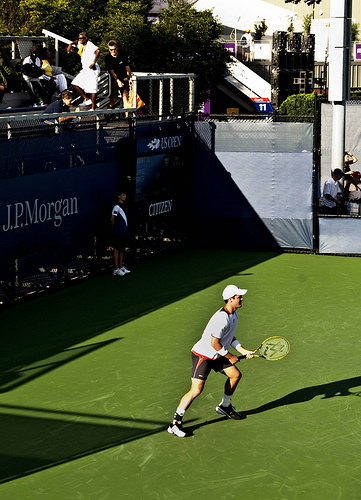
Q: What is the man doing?
A: Playing a sport.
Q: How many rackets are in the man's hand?
A: One.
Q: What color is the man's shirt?
A: White.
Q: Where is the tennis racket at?
A: In the man's hand.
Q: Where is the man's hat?
A: On the mans head.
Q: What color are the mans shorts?
A: Blue and Red.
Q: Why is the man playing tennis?
A: He likes tennis.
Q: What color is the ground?
A: Green.